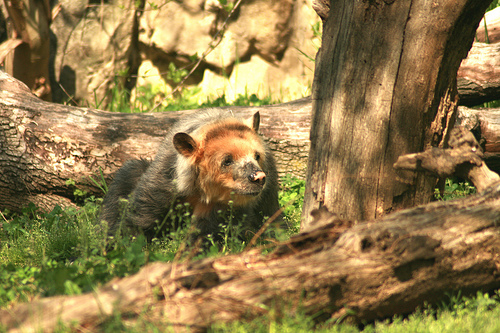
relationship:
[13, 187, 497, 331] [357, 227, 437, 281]
log with holes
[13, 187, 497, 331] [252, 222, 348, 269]
log with openings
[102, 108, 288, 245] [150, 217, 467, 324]
animal surrounded by log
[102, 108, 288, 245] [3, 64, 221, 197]
animal surrounded by log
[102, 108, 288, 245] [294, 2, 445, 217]
animal surrounded by log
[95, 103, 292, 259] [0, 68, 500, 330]
bear laying on ground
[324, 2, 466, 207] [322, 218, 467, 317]
tree behind log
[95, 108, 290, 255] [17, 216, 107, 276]
bear lying in grass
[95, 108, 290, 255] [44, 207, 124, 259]
bear lying in leaves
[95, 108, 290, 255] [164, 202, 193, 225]
bear obscured by flowers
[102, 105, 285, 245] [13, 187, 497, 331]
animal hiding between log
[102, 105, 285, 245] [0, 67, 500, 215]
animal hiding between log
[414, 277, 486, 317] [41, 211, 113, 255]
grass on ground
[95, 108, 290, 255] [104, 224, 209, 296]
bear eating grass